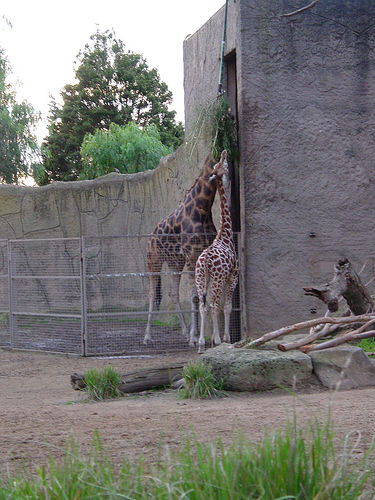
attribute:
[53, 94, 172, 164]
leaves trees — green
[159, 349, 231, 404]
grass — clumped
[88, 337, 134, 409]
grass — horizontal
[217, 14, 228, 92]
pole — metal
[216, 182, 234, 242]
neck — thin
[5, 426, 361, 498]
grass — green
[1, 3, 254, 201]
sky — light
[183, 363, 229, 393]
grass — clumped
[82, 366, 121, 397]
grass — clumped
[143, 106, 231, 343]
giraffes — eating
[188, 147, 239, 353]
giraffes — eating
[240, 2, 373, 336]
wall — tall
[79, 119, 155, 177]
tree — green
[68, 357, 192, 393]
log — horizontal